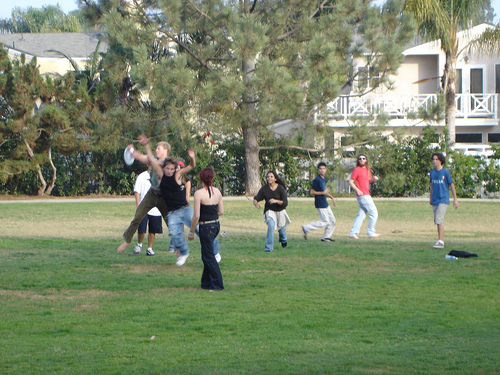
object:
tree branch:
[113, 0, 233, 121]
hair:
[431, 153, 445, 166]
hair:
[356, 154, 370, 175]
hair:
[318, 162, 327, 168]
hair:
[267, 171, 287, 190]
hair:
[200, 168, 214, 198]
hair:
[162, 158, 179, 169]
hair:
[155, 141, 171, 155]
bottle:
[445, 255, 458, 260]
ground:
[0, 196, 500, 375]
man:
[133, 166, 162, 255]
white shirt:
[133, 170, 162, 216]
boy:
[136, 133, 220, 267]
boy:
[348, 154, 378, 239]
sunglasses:
[359, 158, 365, 160]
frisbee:
[124, 146, 135, 165]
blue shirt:
[430, 169, 453, 205]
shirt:
[254, 183, 288, 214]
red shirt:
[351, 166, 370, 196]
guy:
[303, 162, 337, 242]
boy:
[430, 153, 458, 248]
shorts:
[433, 202, 448, 225]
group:
[117, 134, 459, 293]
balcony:
[310, 93, 499, 126]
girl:
[187, 167, 224, 292]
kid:
[253, 171, 289, 252]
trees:
[0, 0, 500, 198]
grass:
[0, 199, 500, 375]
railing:
[315, 92, 495, 119]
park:
[1, 199, 500, 375]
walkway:
[0, 197, 500, 203]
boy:
[118, 141, 181, 258]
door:
[452, 65, 485, 113]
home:
[0, 22, 500, 198]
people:
[118, 134, 457, 289]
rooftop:
[321, 21, 500, 55]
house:
[0, 21, 500, 198]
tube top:
[199, 204, 219, 221]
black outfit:
[199, 205, 219, 223]